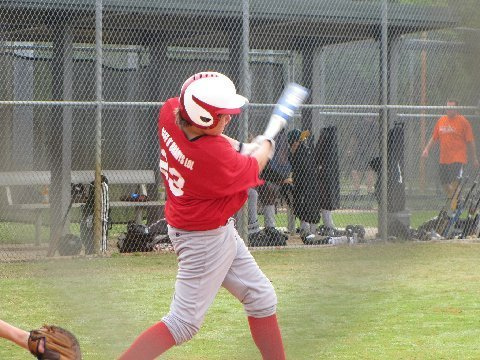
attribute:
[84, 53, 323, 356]
man — young, standing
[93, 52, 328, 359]
baseball player — mid-swing, swinging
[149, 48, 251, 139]
helmet — protective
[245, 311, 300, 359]
socks — red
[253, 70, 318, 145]
bat — metal, blurry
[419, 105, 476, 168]
shirt — red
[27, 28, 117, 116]
fence — gray, wire, tall, dugout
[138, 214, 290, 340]
pants — white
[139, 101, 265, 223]
jersey — red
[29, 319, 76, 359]
mitt — catcher's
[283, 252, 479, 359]
grass — green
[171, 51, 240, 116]
player — baseball player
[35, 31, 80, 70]
mesh — wire